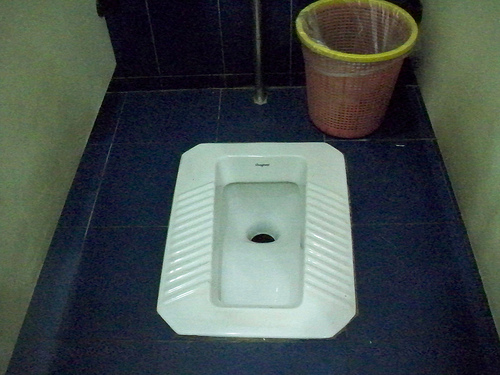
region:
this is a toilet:
[142, 118, 357, 346]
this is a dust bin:
[283, 0, 423, 152]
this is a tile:
[367, 231, 439, 343]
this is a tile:
[87, 210, 153, 315]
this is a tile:
[118, 90, 216, 155]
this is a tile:
[224, 81, 313, 141]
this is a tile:
[69, 293, 151, 370]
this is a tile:
[92, 118, 171, 230]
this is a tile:
[349, 142, 445, 221]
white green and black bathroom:
[3, 3, 495, 374]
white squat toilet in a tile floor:
[155, 139, 360, 342]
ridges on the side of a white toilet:
[301, 179, 358, 314]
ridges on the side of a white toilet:
[158, 177, 217, 307]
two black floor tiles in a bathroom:
[331, 140, 493, 369]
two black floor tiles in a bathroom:
[61, 83, 223, 337]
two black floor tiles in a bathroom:
[97, 69, 292, 91]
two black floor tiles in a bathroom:
[104, 30, 226, 75]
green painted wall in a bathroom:
[1, 0, 116, 367]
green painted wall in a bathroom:
[405, 2, 498, 327]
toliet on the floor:
[150, 130, 358, 343]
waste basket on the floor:
[290, 5, 399, 138]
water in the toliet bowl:
[227, 197, 289, 263]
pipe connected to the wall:
[242, 3, 276, 113]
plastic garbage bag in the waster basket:
[327, 54, 353, 76]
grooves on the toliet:
[167, 179, 207, 299]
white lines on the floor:
[80, 206, 109, 239]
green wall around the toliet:
[19, 33, 79, 140]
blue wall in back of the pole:
[141, 23, 218, 67]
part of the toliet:
[197, 312, 265, 334]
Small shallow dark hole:
[244, 219, 285, 251]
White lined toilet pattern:
[307, 223, 355, 299]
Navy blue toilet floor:
[377, 240, 423, 347]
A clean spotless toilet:
[157, 198, 360, 272]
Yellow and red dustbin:
[333, 46, 404, 73]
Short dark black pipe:
[248, 10, 278, 109]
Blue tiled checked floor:
[101, 120, 156, 187]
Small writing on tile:
[250, 158, 275, 173]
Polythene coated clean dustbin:
[344, 18, 399, 48]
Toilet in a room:
[44, 64, 437, 117]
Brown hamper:
[282, 3, 439, 155]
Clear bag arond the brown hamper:
[287, 0, 428, 98]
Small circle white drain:
[239, 215, 282, 252]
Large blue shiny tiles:
[14, 68, 498, 371]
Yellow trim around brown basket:
[277, 0, 439, 85]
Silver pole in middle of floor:
[233, 1, 276, 111]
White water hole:
[139, 106, 374, 368]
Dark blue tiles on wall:
[89, 1, 404, 109]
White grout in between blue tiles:
[97, 0, 400, 85]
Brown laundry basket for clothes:
[290, 1, 427, 153]